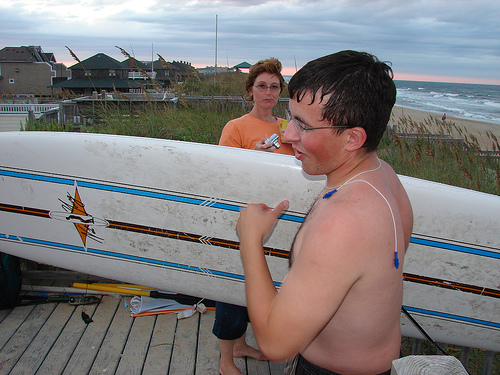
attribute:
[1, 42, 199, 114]
houses — along 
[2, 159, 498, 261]
stripe —  blue, orange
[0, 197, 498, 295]
stripe — blue , orange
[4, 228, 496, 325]
stripe — blue, orange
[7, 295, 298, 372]
wooden deck — brown 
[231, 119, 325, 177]
camera — small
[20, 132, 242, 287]
surfboard — white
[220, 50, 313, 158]
woman — wearing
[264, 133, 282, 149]
camera — silver, small, held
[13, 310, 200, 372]
boardwalk — Wooden 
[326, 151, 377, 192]
neck — around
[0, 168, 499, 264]
stripe — blue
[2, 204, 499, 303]
stripe — blue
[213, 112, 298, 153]
shirt — orange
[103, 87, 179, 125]
leaves — green 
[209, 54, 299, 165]
woman — wearing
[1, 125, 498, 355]
surfboard — red, white, blue,  stripes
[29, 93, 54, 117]
guardrail — wooden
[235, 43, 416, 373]
boy — carrying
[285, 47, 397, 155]
hair — wet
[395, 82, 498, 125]
waves — crashing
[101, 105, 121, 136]
grass — Beach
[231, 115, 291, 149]
shirt — orange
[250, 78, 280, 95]
glasses — eye 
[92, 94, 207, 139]
bushes — covered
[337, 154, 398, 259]
earplugs — pair